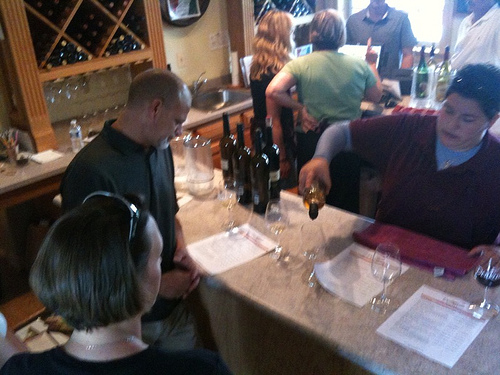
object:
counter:
[50, 148, 500, 374]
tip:
[307, 201, 320, 221]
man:
[297, 63, 500, 277]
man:
[60, 68, 204, 352]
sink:
[189, 80, 256, 114]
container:
[180, 130, 217, 198]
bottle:
[69, 115, 84, 154]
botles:
[261, 125, 283, 203]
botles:
[231, 123, 252, 209]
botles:
[218, 109, 236, 190]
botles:
[300, 174, 326, 221]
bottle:
[248, 119, 273, 213]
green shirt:
[281, 45, 376, 134]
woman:
[264, 8, 387, 216]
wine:
[301, 187, 326, 207]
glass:
[468, 249, 500, 323]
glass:
[367, 241, 408, 315]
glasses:
[82, 187, 145, 241]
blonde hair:
[248, 8, 294, 83]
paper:
[375, 279, 499, 371]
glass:
[296, 216, 327, 287]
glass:
[263, 196, 292, 263]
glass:
[215, 177, 246, 238]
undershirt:
[311, 121, 353, 162]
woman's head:
[29, 190, 163, 323]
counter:
[0, 84, 298, 195]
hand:
[297, 158, 332, 195]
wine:
[474, 267, 500, 286]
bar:
[0, 0, 500, 374]